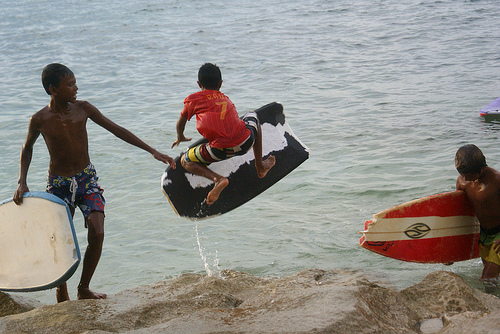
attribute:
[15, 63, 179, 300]
kids — playing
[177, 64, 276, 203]
kids — playing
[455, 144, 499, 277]
kids — playing